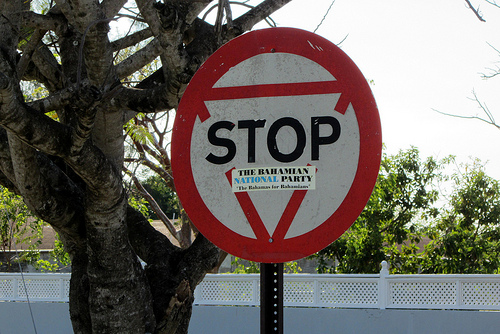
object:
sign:
[166, 25, 383, 264]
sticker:
[229, 165, 317, 193]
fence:
[0, 260, 500, 311]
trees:
[325, 144, 457, 275]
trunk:
[0, 0, 352, 334]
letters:
[203, 116, 342, 166]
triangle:
[192, 79, 359, 242]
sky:
[373, 0, 498, 216]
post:
[259, 261, 283, 334]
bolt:
[268, 238, 274, 243]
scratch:
[305, 39, 316, 50]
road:
[0, 303, 499, 334]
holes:
[327, 292, 331, 296]